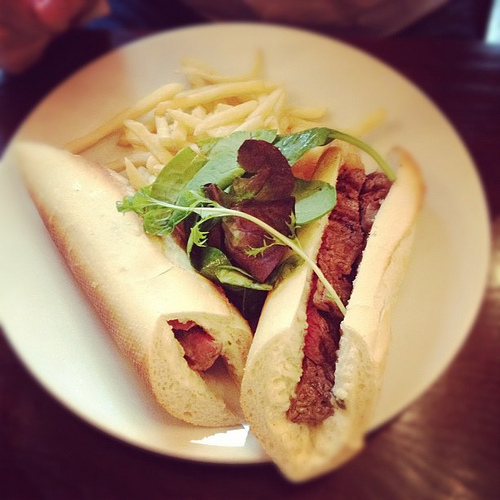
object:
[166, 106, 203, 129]
fries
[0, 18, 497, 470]
plate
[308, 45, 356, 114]
white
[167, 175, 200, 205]
green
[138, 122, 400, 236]
lettuce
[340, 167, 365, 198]
brown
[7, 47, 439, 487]
lunch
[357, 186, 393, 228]
pieces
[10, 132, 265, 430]
bread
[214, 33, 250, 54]
light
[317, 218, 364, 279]
meat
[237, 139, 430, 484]
bun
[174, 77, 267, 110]
fry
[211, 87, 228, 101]
yellow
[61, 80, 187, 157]
frie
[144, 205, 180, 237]
leaf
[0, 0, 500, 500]
table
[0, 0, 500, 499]
wood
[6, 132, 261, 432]
sandwhich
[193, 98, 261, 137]
french fries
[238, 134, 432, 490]
sandwhich